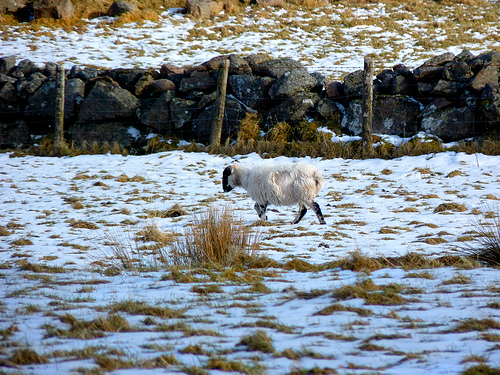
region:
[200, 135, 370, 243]
white sheep in photograph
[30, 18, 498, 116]
stone wall in photograph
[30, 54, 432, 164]
fence on wooden posts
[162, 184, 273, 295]
brown bush in middle of field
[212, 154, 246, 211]
black on white sheeps face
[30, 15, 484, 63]
snowy field behind stone wall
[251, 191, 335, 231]
white sheep has black legs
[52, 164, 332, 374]
green grass poking out of snow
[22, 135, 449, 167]
row of green gras near fence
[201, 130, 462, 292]
one sheep in a field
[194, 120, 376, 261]
a sheep walking on the ground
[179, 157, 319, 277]
a sheep walking on snow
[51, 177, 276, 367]
snow covering the ground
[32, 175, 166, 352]
ground with snow and grass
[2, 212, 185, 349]
snow ontop of the grass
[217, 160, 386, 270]
a sheep standing in the snow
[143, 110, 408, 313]
sheep standing outside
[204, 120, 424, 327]
a white sheep in a field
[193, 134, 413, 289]
a white sheep outside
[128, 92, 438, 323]
a white sheep outside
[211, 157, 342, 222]
The animal is walking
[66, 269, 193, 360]
The ground is white and green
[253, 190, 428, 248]
The animal has black legs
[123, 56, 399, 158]
The stones are in the back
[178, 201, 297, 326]
The grass is tall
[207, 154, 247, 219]
The animal's face is black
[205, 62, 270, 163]
The fence post is wooden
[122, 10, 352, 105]
The ground is patchy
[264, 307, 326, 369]
The snow is white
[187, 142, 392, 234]
The animal is in motion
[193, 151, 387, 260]
sheep is white and black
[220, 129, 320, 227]
sheep has white fur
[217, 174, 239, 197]
sheep has black face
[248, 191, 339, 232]
sheep has black legs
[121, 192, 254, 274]
thin grasses near sheep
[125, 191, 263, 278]
grasses are brown and dormant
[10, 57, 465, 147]
wooden stakes behind sheep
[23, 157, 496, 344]
ground is snow covered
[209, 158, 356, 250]
sheep is walking near stakes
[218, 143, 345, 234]
sheep is mostly white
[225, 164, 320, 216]
black and white sheep walking in snow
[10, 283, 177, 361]
brown grass and white snow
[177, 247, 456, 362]
brown grass and white snow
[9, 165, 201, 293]
brown grass and white snow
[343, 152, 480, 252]
brown grass and white snow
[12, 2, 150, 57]
brown grass and white snow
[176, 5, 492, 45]
brown grass and white snow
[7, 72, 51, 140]
gray rocks and brown snow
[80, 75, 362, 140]
gray rocks and brown snow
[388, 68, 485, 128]
gray rocks and brown snow